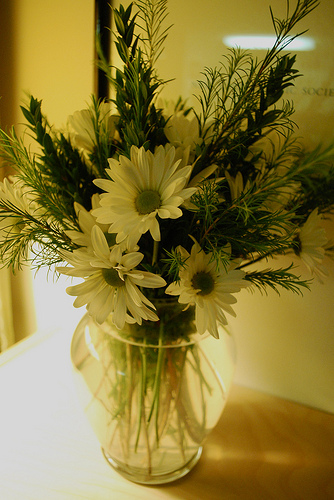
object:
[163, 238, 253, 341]
flower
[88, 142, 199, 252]
flower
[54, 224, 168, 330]
flower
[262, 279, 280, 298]
green leaves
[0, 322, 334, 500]
table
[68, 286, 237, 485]
vase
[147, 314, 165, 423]
stem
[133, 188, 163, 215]
middle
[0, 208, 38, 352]
curtain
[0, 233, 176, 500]
light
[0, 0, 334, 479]
plant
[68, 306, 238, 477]
water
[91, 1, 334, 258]
picture